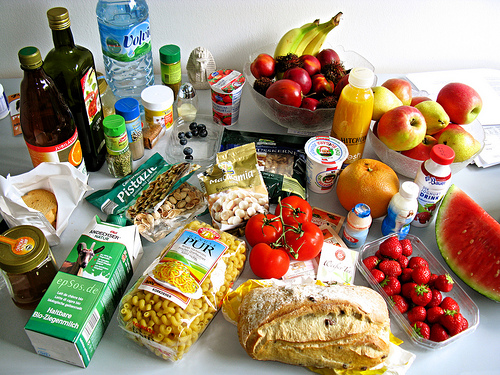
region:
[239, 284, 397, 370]
loaf of bread on table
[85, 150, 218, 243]
bag of pistachios on table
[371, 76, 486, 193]
bin of red and green apples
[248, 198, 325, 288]
four tomatoes on a vine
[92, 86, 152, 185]
jars of spices on table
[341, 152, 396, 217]
orange on a table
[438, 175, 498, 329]
watermelon on a table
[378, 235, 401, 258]
strawberry is next to strawberry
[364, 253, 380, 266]
strawberry is next to strawberry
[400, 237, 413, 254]
strawberry is next to strawberry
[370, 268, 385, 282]
strawberry is next to strawberry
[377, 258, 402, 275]
strawberry is next to strawberry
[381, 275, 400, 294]
strawberry is next to strawberry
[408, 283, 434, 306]
strawberry is next to strawberry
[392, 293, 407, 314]
strawberry is next to strawberry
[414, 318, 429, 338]
strawberry is next to strawberry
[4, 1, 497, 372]
A lot of different food on the table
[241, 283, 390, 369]
A loaf of bread on the table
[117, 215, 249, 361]
A bag of pasta on the table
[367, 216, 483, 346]
A container of strawberries on the table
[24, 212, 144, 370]
A box of milk on the table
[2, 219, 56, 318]
A jar of honey on the table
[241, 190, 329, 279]
Tomatoes are on the table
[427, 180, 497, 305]
A slice of watermelon on the table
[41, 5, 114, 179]
A bottle of olive oil on the table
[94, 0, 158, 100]
A bottle of water on the table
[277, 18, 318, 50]
part of a banana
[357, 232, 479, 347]
a carton of strawberries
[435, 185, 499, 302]
part of a watermelon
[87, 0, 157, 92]
part of a water bottle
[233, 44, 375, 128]
a large clear bowl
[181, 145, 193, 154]
a small blueberry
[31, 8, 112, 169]
a tall glass jar of oil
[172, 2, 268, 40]
part of a painted white wall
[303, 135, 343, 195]
a white container of yogurt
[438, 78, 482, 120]
a large apple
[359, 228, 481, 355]
bunch of strawberries in rectangular clear container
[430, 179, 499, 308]
large cut piece of watermelon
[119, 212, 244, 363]
bag of uncooked pasta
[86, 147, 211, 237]
small square shaped bag of pistachio nuts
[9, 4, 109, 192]
two dark glass bottles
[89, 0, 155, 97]
clear plastic bottle of water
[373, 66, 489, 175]
clear glass bowl of apples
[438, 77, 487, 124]
one sunlit red apple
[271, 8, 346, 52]
three yellow bananas sticking up out of bowl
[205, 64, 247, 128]
one tall container of yogurt